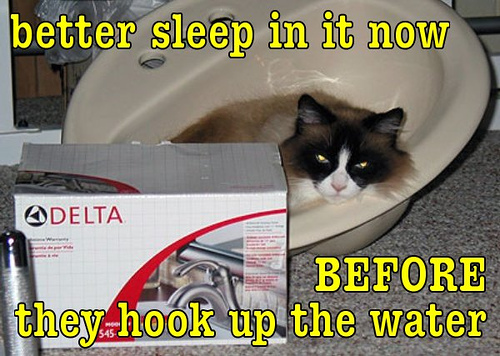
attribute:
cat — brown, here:
[166, 91, 420, 215]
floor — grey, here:
[1, 94, 499, 354]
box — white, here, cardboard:
[15, 140, 292, 346]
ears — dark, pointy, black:
[292, 94, 404, 136]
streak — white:
[335, 142, 349, 183]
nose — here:
[330, 170, 349, 195]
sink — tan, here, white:
[60, 1, 495, 255]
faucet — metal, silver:
[164, 256, 245, 333]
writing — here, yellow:
[10, 10, 488, 336]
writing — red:
[50, 206, 122, 223]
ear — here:
[294, 94, 336, 128]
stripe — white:
[331, 143, 352, 190]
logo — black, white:
[23, 204, 50, 226]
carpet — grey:
[1, 96, 498, 355]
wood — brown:
[10, 2, 66, 98]